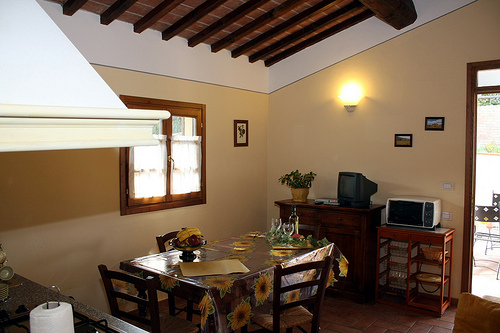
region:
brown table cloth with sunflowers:
[144, 245, 272, 320]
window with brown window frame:
[115, 87, 217, 222]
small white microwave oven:
[381, 190, 455, 234]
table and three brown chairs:
[93, 225, 313, 329]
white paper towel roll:
[22, 287, 78, 331]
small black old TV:
[335, 165, 382, 207]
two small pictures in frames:
[385, 102, 459, 156]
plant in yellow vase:
[277, 162, 313, 197]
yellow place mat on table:
[165, 255, 263, 284]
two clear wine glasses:
[270, 209, 301, 245]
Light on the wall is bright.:
[331, 74, 373, 119]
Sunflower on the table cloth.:
[225, 293, 255, 328]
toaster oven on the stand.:
[386, 193, 441, 228]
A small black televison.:
[334, 161, 380, 209]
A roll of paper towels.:
[21, 283, 80, 332]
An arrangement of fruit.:
[169, 223, 209, 265]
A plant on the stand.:
[279, 159, 314, 204]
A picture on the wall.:
[231, 116, 253, 149]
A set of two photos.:
[387, 104, 450, 151]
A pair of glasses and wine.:
[266, 201, 321, 250]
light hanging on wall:
[335, 66, 367, 113]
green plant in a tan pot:
[278, 164, 317, 203]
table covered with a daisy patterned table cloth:
[120, 223, 350, 330]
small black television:
[336, 169, 378, 204]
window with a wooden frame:
[116, 92, 210, 218]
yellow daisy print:
[221, 296, 255, 332]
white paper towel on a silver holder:
[28, 285, 73, 332]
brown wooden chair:
[271, 255, 335, 332]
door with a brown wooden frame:
[457, 58, 497, 304]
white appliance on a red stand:
[379, 195, 450, 317]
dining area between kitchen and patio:
[21, 15, 474, 317]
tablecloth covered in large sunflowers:
[117, 215, 357, 320]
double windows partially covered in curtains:
[112, 87, 217, 217]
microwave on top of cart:
[375, 185, 457, 317]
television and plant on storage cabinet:
[270, 140, 375, 285]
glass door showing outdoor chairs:
[451, 52, 496, 317]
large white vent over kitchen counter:
[0, 5, 162, 195]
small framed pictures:
[210, 100, 450, 165]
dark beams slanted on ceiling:
[70, 5, 430, 70]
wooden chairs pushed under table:
[101, 197, 336, 323]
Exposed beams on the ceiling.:
[45, 0, 435, 70]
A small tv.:
[330, 160, 385, 215]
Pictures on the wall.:
[385, 100, 450, 165]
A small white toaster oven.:
[380, 185, 445, 235]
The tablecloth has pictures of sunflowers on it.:
[105, 207, 355, 322]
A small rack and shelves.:
[365, 222, 460, 312]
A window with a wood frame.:
[120, 90, 212, 210]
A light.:
[325, 66, 375, 118]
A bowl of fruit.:
[162, 225, 208, 266]